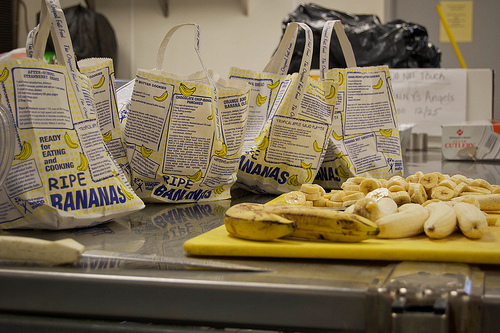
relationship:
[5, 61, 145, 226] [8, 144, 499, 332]
bag on table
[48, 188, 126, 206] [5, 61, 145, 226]
writing on bag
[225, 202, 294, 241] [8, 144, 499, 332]
banana on table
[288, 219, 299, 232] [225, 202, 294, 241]
tip of banana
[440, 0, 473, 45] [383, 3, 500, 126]
notice on door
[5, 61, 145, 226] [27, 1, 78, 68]
bag with handle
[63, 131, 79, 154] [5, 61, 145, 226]
banana on bag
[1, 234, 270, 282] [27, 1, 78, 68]
knife has handle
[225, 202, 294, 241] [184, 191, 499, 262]
banana on cutting board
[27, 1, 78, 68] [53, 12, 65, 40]
handle has writing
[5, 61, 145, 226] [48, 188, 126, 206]
bag with writing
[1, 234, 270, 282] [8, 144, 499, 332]
knife laying on table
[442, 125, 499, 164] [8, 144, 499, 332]
box on table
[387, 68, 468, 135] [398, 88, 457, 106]
paper with writing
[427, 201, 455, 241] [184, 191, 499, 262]
banana on cutting board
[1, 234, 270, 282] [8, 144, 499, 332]
knife on table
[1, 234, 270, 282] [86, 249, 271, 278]
knife has blade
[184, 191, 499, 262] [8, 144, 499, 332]
cutting board on table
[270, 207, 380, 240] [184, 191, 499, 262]
banana on cutting board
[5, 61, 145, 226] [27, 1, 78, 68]
bag has handle